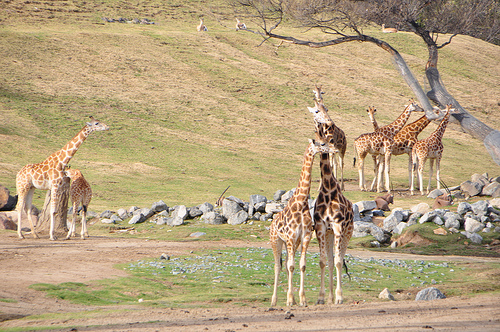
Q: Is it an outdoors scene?
A: Yes, it is outdoors.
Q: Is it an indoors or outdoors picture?
A: It is outdoors.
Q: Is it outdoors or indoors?
A: It is outdoors.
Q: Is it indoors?
A: No, it is outdoors.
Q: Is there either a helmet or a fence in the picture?
A: No, there are no fences or helmets.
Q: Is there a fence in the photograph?
A: No, there are no fences.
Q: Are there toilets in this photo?
A: No, there are no toilets.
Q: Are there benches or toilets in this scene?
A: No, there are no toilets or benches.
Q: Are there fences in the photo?
A: No, there are no fences.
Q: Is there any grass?
A: Yes, there is grass.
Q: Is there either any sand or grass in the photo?
A: Yes, there is grass.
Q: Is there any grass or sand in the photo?
A: Yes, there is grass.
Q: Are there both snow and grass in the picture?
A: No, there is grass but no snow.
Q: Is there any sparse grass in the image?
A: Yes, there is sparse grass.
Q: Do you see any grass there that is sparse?
A: Yes, there is grass that is sparse.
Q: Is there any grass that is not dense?
A: Yes, there is sparse grass.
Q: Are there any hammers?
A: No, there are no hammers.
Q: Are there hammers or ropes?
A: No, there are no hammers or ropes.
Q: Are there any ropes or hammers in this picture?
A: No, there are no hammers or ropes.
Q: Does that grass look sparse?
A: Yes, the grass is sparse.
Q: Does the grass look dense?
A: No, the grass is sparse.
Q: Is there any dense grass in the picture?
A: No, there is grass but it is sparse.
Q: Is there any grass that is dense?
A: No, there is grass but it is sparse.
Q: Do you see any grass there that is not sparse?
A: No, there is grass but it is sparse.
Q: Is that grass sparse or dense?
A: The grass is sparse.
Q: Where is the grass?
A: The grass is on the hill.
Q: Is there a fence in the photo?
A: No, there are no fences.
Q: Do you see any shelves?
A: No, there are no shelves.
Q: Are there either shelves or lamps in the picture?
A: No, there are no shelves or lamps.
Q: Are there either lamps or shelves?
A: No, there are no shelves or lamps.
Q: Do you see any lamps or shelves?
A: No, there are no shelves or lamps.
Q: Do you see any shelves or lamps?
A: No, there are no shelves or lamps.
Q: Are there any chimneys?
A: No, there are no chimneys.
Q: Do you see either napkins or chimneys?
A: No, there are no chimneys or napkins.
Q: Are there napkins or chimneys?
A: No, there are no chimneys or napkins.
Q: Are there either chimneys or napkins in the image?
A: No, there are no chimneys or napkins.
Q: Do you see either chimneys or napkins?
A: No, there are no chimneys or napkins.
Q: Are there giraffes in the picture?
A: Yes, there are giraffes.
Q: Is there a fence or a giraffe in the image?
A: Yes, there are giraffes.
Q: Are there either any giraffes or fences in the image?
A: Yes, there are giraffes.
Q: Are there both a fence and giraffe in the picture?
A: No, there are giraffes but no fences.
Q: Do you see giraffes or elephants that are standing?
A: Yes, the giraffes are standing.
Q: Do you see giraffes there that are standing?
A: Yes, there are giraffes that are standing.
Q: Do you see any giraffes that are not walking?
A: Yes, there are giraffes that are standing .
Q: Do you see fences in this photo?
A: No, there are no fences.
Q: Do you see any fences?
A: No, there are no fences.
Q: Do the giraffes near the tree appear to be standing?
A: Yes, the giraffes are standing.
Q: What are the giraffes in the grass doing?
A: The giraffes are standing.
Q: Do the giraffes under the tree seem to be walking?
A: No, the giraffes are standing.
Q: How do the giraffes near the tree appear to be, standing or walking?
A: The giraffes are standing.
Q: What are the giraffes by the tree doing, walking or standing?
A: The giraffes are standing.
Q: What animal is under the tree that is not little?
A: The giraffes are under the tree.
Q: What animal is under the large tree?
A: The giraffes are under the tree.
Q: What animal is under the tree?
A: The giraffes are under the tree.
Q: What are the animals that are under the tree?
A: The animals are giraffes.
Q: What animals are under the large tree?
A: The animals are giraffes.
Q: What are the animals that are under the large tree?
A: The animals are giraffes.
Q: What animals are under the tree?
A: The animals are giraffes.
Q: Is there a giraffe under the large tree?
A: Yes, there are giraffes under the tree.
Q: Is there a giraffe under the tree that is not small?
A: Yes, there are giraffes under the tree.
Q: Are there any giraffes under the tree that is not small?
A: Yes, there are giraffes under the tree.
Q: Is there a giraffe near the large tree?
A: Yes, there are giraffes near the tree.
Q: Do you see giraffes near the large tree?
A: Yes, there are giraffes near the tree.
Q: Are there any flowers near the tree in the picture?
A: No, there are giraffes near the tree.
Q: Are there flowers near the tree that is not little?
A: No, there are giraffes near the tree.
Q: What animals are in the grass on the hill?
A: The animals are giraffes.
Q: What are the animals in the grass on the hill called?
A: The animals are giraffes.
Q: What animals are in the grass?
A: The animals are giraffes.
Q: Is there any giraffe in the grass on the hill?
A: Yes, there are giraffes in the grass.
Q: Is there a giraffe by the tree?
A: Yes, there are giraffes by the tree.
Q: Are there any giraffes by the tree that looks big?
A: Yes, there are giraffes by the tree.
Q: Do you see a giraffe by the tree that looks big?
A: Yes, there are giraffes by the tree.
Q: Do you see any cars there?
A: No, there are no cars.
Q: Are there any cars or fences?
A: No, there are no cars or fences.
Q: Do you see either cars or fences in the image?
A: No, there are no cars or fences.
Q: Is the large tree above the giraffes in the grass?
A: Yes, the tree is above the giraffes.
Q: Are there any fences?
A: No, there are no fences.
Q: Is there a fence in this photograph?
A: No, there are no fences.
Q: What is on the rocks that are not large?
A: The moss is on the rocks.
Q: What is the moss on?
A: The moss is on the rocks.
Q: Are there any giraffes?
A: Yes, there is a giraffe.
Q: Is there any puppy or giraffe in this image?
A: Yes, there is a giraffe.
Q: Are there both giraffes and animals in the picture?
A: Yes, there are both a giraffe and an animal.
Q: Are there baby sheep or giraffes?
A: Yes, there is a baby giraffe.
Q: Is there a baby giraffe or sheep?
A: Yes, there is a baby giraffe.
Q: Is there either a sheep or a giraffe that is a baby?
A: Yes, the giraffe is a baby.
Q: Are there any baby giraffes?
A: Yes, there is a baby giraffe.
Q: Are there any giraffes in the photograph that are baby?
A: Yes, there is a giraffe that is a baby.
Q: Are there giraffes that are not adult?
A: Yes, there is an baby giraffe.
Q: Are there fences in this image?
A: No, there are no fences.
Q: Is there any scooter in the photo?
A: No, there are no scooters.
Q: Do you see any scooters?
A: No, there are no scooters.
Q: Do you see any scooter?
A: No, there are no scooters.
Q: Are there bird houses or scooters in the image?
A: No, there are no scooters or bird houses.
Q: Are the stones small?
A: Yes, the stones are small.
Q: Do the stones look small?
A: Yes, the stones are small.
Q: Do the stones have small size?
A: Yes, the stones are small.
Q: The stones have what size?
A: The stones are small.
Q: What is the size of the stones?
A: The stones are small.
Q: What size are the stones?
A: The stones are small.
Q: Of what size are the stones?
A: The stones are small.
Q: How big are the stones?
A: The stones are small.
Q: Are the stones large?
A: No, the stones are small.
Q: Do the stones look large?
A: No, the stones are small.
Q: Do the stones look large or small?
A: The stones are small.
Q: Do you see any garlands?
A: No, there are no garlands.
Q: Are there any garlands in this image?
A: No, there are no garlands.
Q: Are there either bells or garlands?
A: No, there are no garlands or bells.